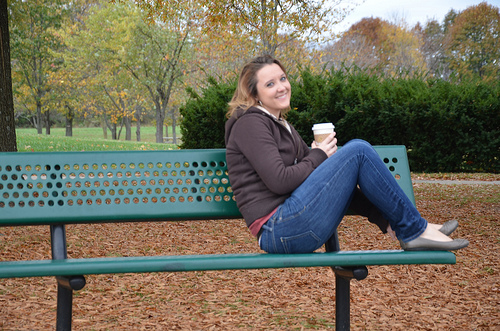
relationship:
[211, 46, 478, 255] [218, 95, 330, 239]
woman wearing sweater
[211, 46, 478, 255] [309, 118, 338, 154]
woman holding cup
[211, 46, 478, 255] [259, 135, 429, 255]
woman wearing jeans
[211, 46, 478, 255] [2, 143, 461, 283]
woman sitting on bench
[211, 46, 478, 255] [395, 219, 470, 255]
woman wearing flats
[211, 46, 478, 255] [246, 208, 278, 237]
woman wearing shirt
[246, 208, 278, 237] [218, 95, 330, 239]
shirt under sweater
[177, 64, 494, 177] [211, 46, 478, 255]
bushes behind woman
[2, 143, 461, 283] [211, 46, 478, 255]
bench under woman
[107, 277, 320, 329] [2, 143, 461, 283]
leaves around bench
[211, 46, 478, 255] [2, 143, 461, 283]
woman on bench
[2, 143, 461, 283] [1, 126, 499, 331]
bench at park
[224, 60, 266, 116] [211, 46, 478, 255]
hair of woman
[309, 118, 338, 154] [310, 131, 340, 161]
cup in hand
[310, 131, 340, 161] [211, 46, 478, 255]
hand of woman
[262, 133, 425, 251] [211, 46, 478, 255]
legs of woman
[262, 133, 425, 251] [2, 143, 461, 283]
legs on bench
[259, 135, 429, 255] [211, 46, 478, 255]
jeans of woman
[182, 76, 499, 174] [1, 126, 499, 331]
hedge in park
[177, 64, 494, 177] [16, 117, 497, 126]
bush in background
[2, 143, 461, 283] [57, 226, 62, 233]
bench made of metal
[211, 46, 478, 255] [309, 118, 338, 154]
woman holding coffee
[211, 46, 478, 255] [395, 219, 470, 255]
woman wearing shoes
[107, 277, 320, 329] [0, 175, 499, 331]
leaves on ground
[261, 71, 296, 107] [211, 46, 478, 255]
face of girl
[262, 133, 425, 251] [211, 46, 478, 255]
legs of girl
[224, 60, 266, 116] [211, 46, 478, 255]
hair of girl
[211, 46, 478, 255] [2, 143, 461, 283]
girl sitting in chair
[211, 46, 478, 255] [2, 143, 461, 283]
girl in chair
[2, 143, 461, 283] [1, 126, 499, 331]
bench in park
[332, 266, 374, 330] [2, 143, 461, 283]
leg of bench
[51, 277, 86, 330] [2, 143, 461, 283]
leg of bench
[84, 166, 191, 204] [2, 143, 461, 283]
holes in bench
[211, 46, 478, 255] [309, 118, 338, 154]
girl holding cup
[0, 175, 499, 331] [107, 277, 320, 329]
ground covered in leaves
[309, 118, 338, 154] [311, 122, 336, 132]
cup has lid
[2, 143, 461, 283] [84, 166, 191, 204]
bench has holes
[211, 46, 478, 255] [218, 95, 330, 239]
she wearing sweatshirt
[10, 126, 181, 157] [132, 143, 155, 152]
grass with leaves